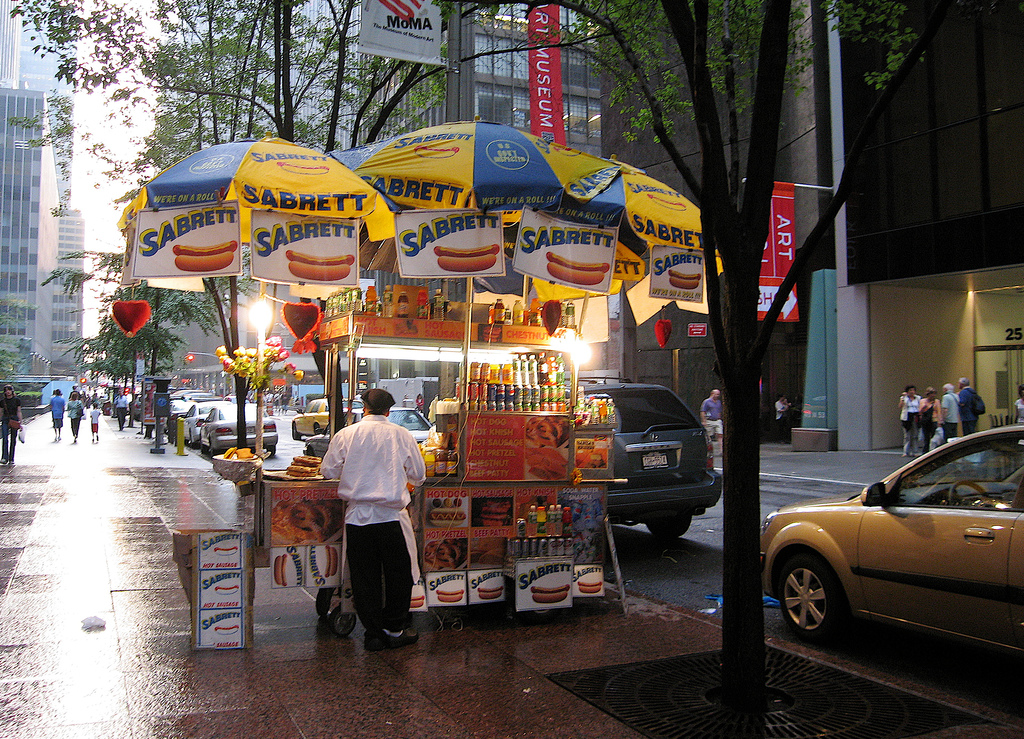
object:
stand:
[187, 460, 633, 651]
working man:
[322, 390, 430, 652]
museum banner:
[432, 0, 624, 151]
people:
[47, 386, 146, 445]